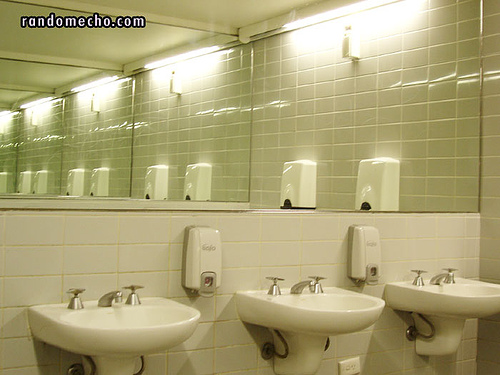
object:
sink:
[27, 283, 201, 373]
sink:
[386, 267, 499, 359]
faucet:
[95, 283, 149, 307]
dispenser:
[339, 216, 399, 293]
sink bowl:
[25, 293, 203, 362]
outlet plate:
[339, 356, 363, 374]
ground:
[317, 173, 318, 218]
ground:
[381, 161, 388, 173]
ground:
[413, 138, 441, 159]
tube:
[134, 354, 149, 374]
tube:
[83, 354, 97, 374]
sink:
[237, 285, 384, 373]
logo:
[202, 242, 218, 253]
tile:
[402, 81, 429, 106]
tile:
[353, 91, 376, 109]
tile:
[333, 140, 354, 160]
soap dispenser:
[183, 226, 225, 299]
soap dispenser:
[347, 224, 385, 287]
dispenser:
[181, 227, 226, 300]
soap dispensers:
[354, 153, 403, 212]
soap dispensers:
[279, 157, 316, 210]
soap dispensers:
[183, 162, 211, 202]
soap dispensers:
[141, 165, 168, 202]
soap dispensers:
[88, 167, 110, 198]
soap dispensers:
[67, 167, 84, 197]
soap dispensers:
[31, 167, 48, 198]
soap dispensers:
[16, 170, 31, 194]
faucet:
[430, 268, 462, 289]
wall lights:
[233, 0, 419, 43]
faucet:
[288, 275, 330, 296]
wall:
[0, 214, 483, 375]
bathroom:
[0, 6, 498, 375]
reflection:
[0, 4, 500, 211]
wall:
[1, 4, 498, 372]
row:
[21, 263, 498, 370]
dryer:
[352, 155, 401, 214]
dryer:
[275, 153, 324, 213]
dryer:
[179, 156, 219, 204]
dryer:
[137, 164, 172, 203]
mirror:
[5, 1, 492, 217]